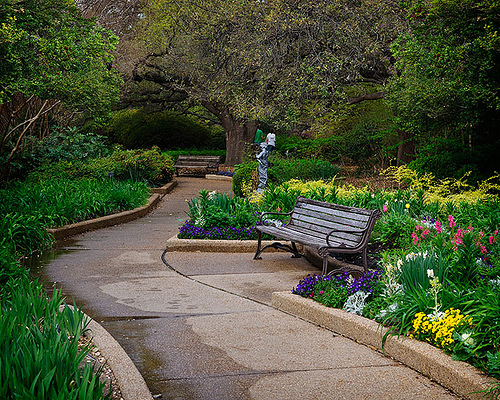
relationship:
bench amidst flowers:
[252, 194, 380, 285] [184, 177, 499, 377]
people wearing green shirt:
[251, 124, 268, 158] [254, 126, 262, 141]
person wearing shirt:
[265, 127, 275, 150] [264, 132, 276, 145]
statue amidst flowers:
[257, 131, 277, 193] [173, 189, 358, 248]